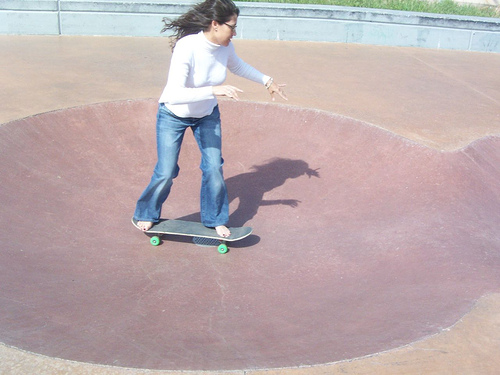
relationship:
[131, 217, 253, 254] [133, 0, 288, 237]
skateboard under woman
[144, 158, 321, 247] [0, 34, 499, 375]
shadow on ground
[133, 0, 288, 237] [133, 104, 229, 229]
woman wearing jeans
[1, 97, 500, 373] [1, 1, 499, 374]
ramp at skatepark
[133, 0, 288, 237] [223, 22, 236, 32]
woman has glasses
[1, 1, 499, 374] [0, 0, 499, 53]
skatepark has a fence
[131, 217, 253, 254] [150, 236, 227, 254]
skateboard has wheels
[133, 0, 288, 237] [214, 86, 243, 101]
woman has a right hand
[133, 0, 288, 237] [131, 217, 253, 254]
woman on a skateboard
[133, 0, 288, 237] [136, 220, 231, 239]
woman has bare feet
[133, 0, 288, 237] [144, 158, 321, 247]
woman has a shadow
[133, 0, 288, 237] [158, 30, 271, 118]
woman wearing a sweater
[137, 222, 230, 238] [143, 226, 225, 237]
toes have nail polish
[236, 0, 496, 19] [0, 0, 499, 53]
leaves are behind fence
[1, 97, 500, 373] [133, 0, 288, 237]
ramp for skateboarding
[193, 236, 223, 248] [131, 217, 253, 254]
drain below skateboard